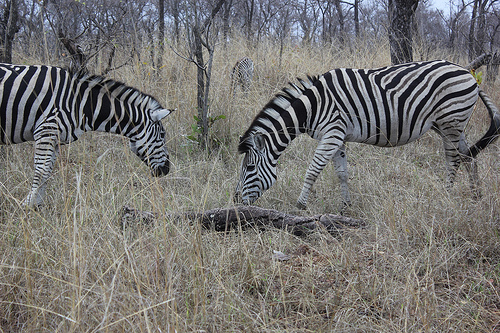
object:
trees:
[384, 0, 420, 67]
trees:
[0, 0, 53, 64]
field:
[0, 45, 499, 332]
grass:
[0, 24, 499, 332]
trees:
[31, 0, 149, 71]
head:
[129, 107, 175, 178]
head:
[231, 131, 280, 208]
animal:
[0, 61, 175, 211]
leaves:
[188, 114, 203, 125]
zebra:
[229, 55, 255, 96]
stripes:
[343, 68, 372, 141]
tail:
[458, 90, 500, 162]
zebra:
[0, 63, 175, 212]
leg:
[432, 101, 474, 192]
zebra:
[231, 60, 499, 215]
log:
[114, 204, 369, 242]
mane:
[235, 72, 320, 156]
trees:
[148, 0, 227, 152]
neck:
[261, 84, 307, 152]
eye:
[244, 163, 257, 173]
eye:
[157, 130, 167, 140]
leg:
[330, 141, 355, 216]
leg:
[20, 116, 61, 212]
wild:
[0, 0, 499, 332]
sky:
[0, 0, 499, 47]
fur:
[0, 63, 176, 212]